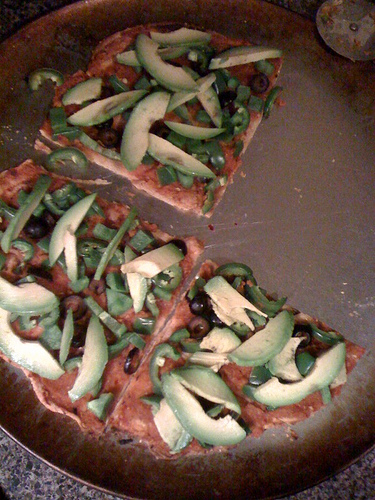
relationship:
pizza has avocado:
[35, 23, 287, 221] [132, 32, 202, 94]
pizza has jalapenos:
[35, 23, 287, 221] [25, 65, 67, 93]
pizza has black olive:
[35, 23, 287, 221] [247, 73, 272, 96]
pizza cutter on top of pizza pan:
[315, 1, 374, 61] [1, 1, 373, 499]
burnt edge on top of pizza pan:
[0, 362, 374, 500] [1, 1, 373, 499]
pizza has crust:
[35, 23, 287, 221] [44, 18, 277, 133]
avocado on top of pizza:
[132, 32, 202, 94] [35, 23, 287, 221]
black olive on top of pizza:
[247, 73, 272, 96] [35, 23, 287, 221]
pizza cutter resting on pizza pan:
[315, 1, 374, 61] [1, 1, 373, 499]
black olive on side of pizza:
[247, 73, 272, 96] [35, 23, 287, 221]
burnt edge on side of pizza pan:
[0, 362, 374, 500] [1, 1, 373, 499]